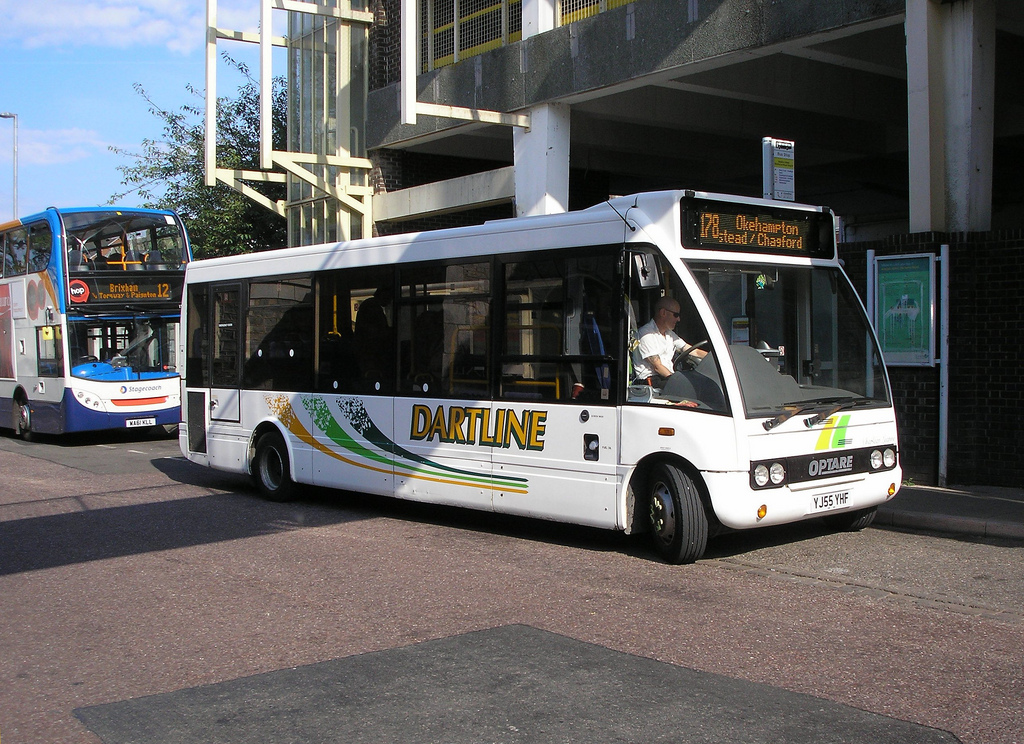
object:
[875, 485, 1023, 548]
curb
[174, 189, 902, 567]
bus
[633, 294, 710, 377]
driver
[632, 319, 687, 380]
shirt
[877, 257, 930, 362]
sign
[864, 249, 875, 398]
pole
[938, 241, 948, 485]
pole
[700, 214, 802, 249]
lights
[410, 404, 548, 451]
dartline writing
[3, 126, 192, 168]
clouds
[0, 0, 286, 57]
clouds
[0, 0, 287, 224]
sky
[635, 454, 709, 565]
tire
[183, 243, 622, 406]
window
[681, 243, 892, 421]
window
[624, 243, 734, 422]
window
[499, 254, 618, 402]
window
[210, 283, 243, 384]
window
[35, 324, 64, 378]
window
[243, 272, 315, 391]
window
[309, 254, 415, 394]
window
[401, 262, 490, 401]
window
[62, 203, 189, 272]
window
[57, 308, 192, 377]
window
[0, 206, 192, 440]
bus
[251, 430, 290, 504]
wheel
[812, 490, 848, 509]
license plate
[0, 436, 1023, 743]
street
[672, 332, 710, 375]
steering wheel